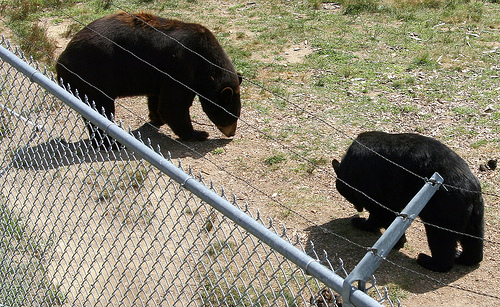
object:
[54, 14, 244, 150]
bear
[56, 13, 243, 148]
fur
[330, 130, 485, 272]
bear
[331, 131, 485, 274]
fur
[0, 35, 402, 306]
fence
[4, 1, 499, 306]
ground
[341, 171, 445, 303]
bracket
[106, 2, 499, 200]
wire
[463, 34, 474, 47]
foliage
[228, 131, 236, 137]
nose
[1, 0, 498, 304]
dirt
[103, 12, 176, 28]
patch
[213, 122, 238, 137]
snout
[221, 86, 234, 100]
ear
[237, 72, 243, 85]
ear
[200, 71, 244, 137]
head